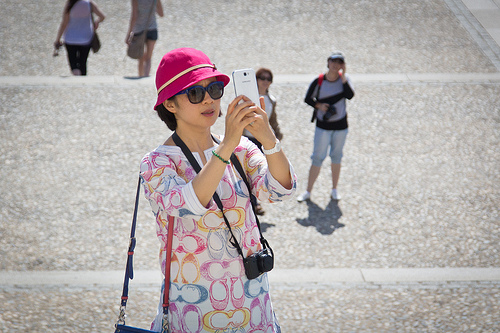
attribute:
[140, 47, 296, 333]
woman — standing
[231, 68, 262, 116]
camera — in front, black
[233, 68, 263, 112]
phone — white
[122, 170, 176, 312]
strap — blue, black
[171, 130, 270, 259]
strap — black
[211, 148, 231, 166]
bracelet — green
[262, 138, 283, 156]
watch — white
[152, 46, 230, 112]
hat — pink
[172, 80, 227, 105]
glasses — blue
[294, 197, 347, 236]
shadow — woman in background's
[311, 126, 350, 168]
shorts — blue